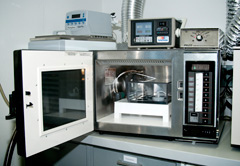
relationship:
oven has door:
[4, 49, 225, 160] [5, 50, 95, 159]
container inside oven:
[124, 81, 172, 105] [4, 49, 225, 160]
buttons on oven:
[188, 72, 208, 125] [4, 49, 225, 160]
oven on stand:
[4, 49, 225, 160] [26, 121, 239, 166]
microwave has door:
[4, 49, 225, 160] [5, 50, 95, 159]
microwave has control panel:
[4, 49, 225, 160] [184, 61, 215, 128]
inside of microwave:
[97, 62, 172, 128] [4, 49, 225, 160]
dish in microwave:
[124, 81, 172, 105] [4, 49, 225, 160]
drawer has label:
[93, 148, 178, 166] [123, 155, 138, 164]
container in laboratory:
[124, 81, 172, 105] [0, 1, 239, 166]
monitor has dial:
[180, 28, 227, 51] [196, 34, 203, 41]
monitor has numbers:
[180, 28, 227, 51] [190, 30, 210, 44]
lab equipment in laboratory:
[5, 10, 228, 158] [0, 1, 239, 166]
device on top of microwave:
[128, 18, 183, 49] [185, 61, 214, 127]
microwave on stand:
[4, 49, 225, 160] [26, 121, 239, 166]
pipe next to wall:
[3, 129, 18, 166] [1, 0, 227, 166]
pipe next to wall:
[1, 85, 10, 108] [1, 0, 227, 166]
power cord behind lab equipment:
[224, 70, 232, 123] [5, 10, 228, 158]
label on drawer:
[123, 155, 138, 164] [93, 148, 178, 166]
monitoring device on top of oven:
[128, 18, 183, 49] [4, 49, 225, 160]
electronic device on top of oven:
[180, 28, 227, 51] [4, 49, 225, 160]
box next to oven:
[230, 46, 239, 148] [4, 49, 225, 160]